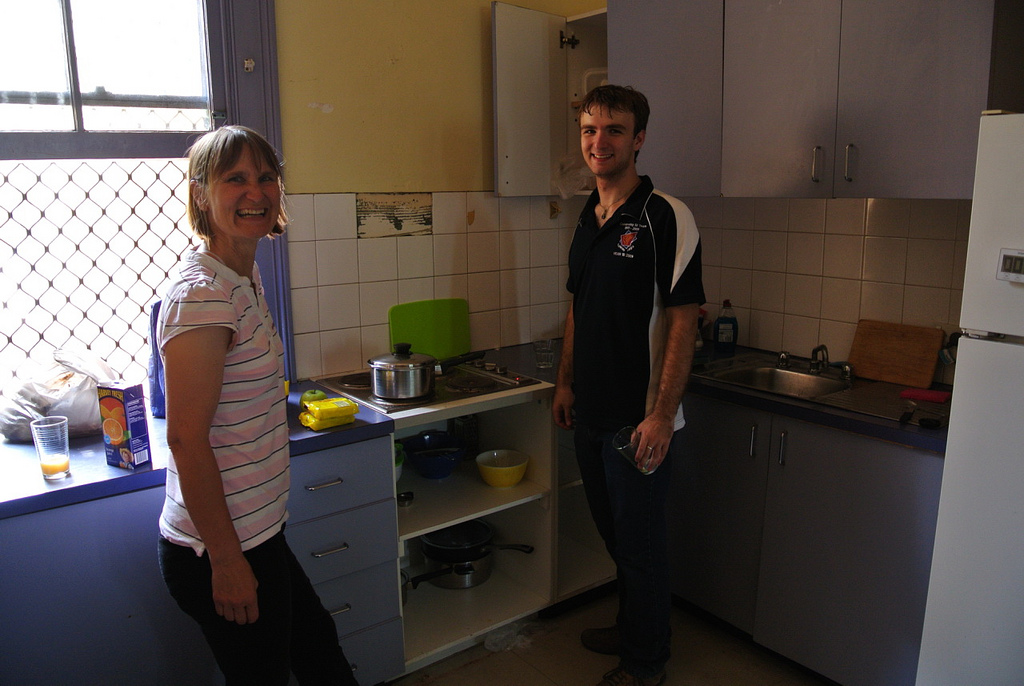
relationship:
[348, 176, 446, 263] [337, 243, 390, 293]
bare area of wall missing two tiles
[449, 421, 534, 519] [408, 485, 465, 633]
mixing bowl on shelf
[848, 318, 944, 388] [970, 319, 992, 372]
board leaning against wall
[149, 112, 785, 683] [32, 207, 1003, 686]
two people standing in a kitchen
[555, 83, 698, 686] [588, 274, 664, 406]
man with a black and white shirt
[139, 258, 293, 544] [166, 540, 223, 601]
shirt shirt pink and white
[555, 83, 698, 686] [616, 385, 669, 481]
man holding glass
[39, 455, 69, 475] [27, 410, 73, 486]
juice in glass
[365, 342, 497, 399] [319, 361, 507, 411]
black burner on a black burner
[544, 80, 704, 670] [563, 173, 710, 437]
man wearing shirt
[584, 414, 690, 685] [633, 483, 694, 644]
jeans man wearing jeans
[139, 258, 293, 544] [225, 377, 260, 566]
shirt shirt has stripes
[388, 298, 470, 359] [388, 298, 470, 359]
board cutting board board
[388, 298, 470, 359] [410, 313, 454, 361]
board a cutting board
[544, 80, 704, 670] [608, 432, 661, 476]
man holding glass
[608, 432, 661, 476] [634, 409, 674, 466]
glass in hand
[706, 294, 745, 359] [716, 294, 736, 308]
bottle with cap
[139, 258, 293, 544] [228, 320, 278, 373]
shirt with lines